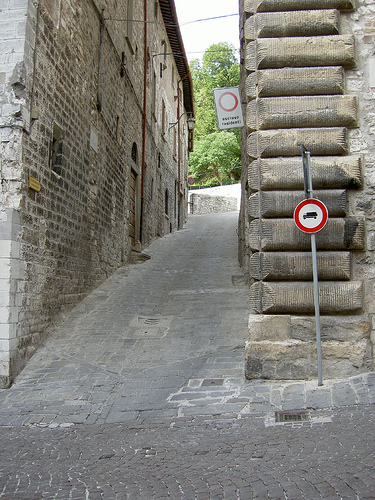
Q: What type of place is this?
A: It is a road.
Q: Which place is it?
A: It is a road.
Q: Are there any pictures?
A: No, there are no pictures.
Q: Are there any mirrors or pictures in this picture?
A: No, there are no pictures or mirrors.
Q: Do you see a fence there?
A: No, there are no fences.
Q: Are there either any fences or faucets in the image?
A: No, there are no fences or faucets.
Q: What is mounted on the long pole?
A: The sign is mounted on the pole.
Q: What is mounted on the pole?
A: The sign is mounted on the pole.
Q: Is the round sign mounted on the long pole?
A: Yes, the sign is mounted on the pole.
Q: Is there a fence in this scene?
A: No, there are no fences.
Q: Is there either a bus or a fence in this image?
A: No, there are no fences or buses.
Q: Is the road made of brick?
A: Yes, the road is made of brick.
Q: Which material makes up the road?
A: The road is made of brick.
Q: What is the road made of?
A: The road is made of brick.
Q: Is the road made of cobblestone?
A: No, the road is made of brick.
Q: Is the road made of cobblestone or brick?
A: The road is made of brick.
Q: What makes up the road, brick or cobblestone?
A: The road is made of brick.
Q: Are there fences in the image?
A: No, there are no fences.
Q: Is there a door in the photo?
A: Yes, there is a door.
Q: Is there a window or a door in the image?
A: Yes, there is a door.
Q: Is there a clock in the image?
A: No, there are no clocks.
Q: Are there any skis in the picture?
A: No, there are no skis.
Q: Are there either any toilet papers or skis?
A: No, there are no skis or toilet papers.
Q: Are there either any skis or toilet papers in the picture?
A: No, there are no skis or toilet papers.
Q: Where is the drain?
A: The drain is on the road.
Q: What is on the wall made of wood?
A: The sign is on the wall.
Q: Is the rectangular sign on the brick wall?
A: Yes, the sign is on the wall.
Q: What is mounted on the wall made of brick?
A: The sign is mounted on the wall.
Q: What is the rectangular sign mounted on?
A: The sign is mounted on the wall.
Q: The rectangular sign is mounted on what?
A: The sign is mounted on the wall.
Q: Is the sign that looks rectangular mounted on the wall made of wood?
A: Yes, the sign is mounted on the wall.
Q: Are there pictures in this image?
A: No, there are no pictures.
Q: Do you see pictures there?
A: No, there are no pictures.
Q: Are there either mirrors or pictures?
A: No, there are no pictures or mirrors.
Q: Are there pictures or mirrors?
A: No, there are no pictures or mirrors.